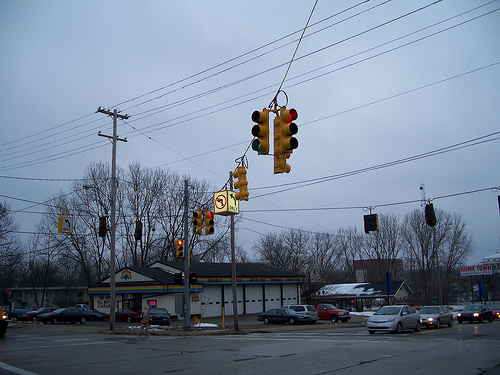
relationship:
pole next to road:
[95, 106, 131, 333] [0, 318, 499, 375]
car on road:
[365, 303, 423, 335] [0, 318, 499, 375]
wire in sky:
[0, 0, 366, 148] [1, 0, 498, 281]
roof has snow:
[305, 280, 413, 300] [314, 282, 382, 296]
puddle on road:
[103, 335, 139, 347] [0, 318, 499, 375]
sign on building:
[147, 299, 157, 307] [92, 260, 306, 318]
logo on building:
[118, 267, 131, 284] [92, 260, 306, 318]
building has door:
[92, 260, 306, 318] [120, 293, 142, 316]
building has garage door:
[92, 260, 306, 318] [199, 282, 224, 319]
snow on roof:
[314, 282, 382, 296] [305, 280, 413, 300]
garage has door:
[192, 277, 303, 319] [224, 282, 247, 317]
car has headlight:
[416, 305, 454, 330] [427, 316, 434, 324]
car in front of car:
[365, 303, 423, 335] [416, 305, 454, 330]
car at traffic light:
[365, 303, 423, 335] [274, 104, 299, 158]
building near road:
[92, 260, 306, 318] [0, 318, 499, 375]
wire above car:
[0, 0, 366, 148] [365, 303, 423, 335]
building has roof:
[300, 278, 413, 311] [305, 280, 413, 300]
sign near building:
[458, 262, 494, 279] [300, 278, 413, 311]